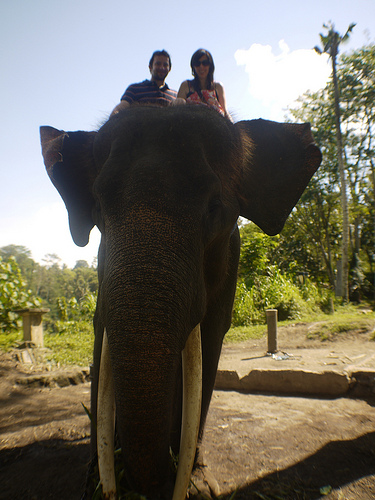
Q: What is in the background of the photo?
A: Trees.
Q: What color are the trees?
A: Green.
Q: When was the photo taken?
A: Daytime.